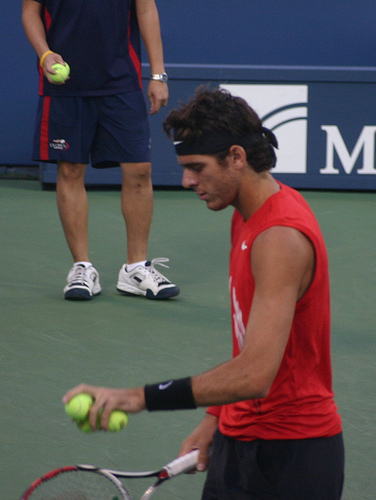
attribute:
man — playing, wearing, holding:
[113, 95, 351, 471]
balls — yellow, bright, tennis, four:
[57, 366, 121, 439]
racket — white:
[47, 455, 207, 496]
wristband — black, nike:
[144, 382, 199, 414]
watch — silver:
[131, 60, 195, 90]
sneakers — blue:
[51, 255, 185, 331]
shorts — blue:
[52, 82, 190, 195]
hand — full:
[90, 396, 163, 419]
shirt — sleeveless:
[224, 214, 365, 463]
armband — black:
[135, 382, 225, 433]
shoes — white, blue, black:
[54, 254, 155, 333]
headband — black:
[163, 110, 314, 179]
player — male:
[160, 89, 329, 368]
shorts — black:
[210, 429, 319, 494]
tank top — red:
[233, 214, 339, 392]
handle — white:
[163, 432, 225, 487]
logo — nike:
[149, 364, 190, 399]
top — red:
[211, 189, 309, 297]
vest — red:
[233, 335, 314, 399]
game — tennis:
[14, 15, 334, 420]